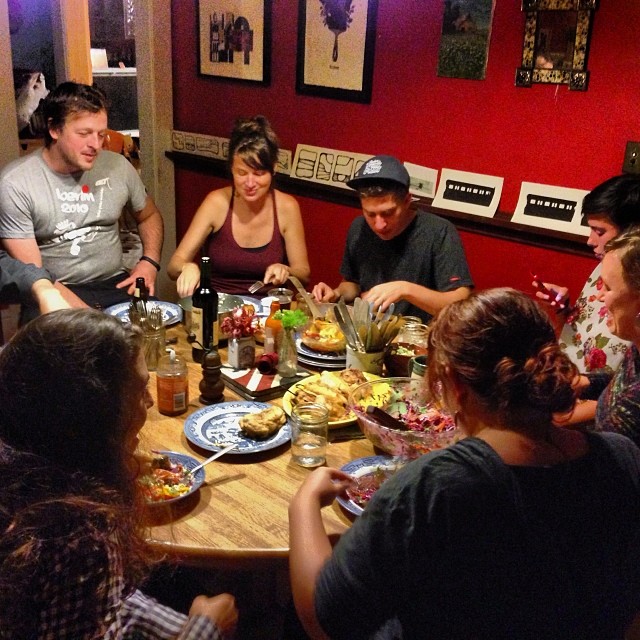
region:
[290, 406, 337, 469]
a glass on the table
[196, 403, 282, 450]
a blue plate on the table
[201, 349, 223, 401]
a salt shaker on the table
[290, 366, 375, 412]
a yellow plate on the table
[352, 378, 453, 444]
a bowl on the table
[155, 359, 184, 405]
a jar on the table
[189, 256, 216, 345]
a bottle of wine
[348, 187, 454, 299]
a man in a grey shirt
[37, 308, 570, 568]
a wooden table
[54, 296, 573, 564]
a table with food on it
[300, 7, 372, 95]
a picture on the wall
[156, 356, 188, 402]
a bottle on the table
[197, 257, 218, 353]
a wine bottle on the table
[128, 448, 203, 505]
a plate of food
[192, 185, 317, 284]
a lady in a red shirt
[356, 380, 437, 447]
a glass bowl on the table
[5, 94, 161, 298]
a man sitting at the table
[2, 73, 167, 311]
Man with gray graphic shirt sitting at dining room table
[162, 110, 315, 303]
Woman with purple tank top sitting at dining room table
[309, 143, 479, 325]
Man with dark gray shirt and cap sitting at dining room table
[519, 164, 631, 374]
Person with short dark hair looking at cell phone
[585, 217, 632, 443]
Person sitting at dining room table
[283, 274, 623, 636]
Woman with long brown hair sitting at dining room table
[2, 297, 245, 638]
Woman with print dress and long hair sitting at dining room table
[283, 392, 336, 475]
Beverage glass sitting on dining room table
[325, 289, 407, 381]
Mug with eating utensils sitting on dining room table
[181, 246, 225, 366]
Wine bottle sitting on dining room table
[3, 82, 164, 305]
man in gray shirt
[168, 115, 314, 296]
woman wearing maroon tank top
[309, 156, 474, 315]
man wearing black baseball cap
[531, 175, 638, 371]
man checking his cell phone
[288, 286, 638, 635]
woman wearing black shirt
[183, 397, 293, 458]
decorative blue and white plate with food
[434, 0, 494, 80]
painting of a farm scene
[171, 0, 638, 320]
paintings hanging on red well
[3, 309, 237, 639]
person wearing blue checkered shirt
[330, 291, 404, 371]
white cup containing silverware